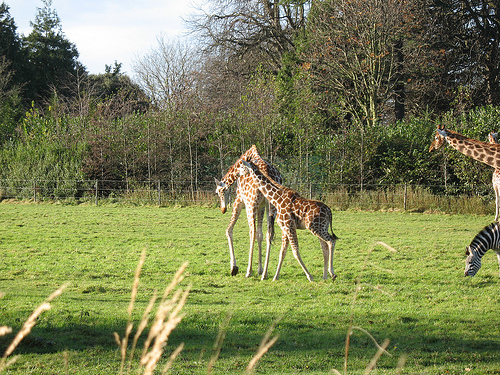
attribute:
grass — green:
[0, 189, 497, 372]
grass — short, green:
[5, 209, 221, 329]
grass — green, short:
[340, 214, 452, 366]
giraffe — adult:
[246, 192, 336, 275]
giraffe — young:
[195, 142, 263, 259]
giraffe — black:
[184, 142, 367, 289]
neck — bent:
[214, 140, 262, 210]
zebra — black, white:
[460, 224, 499, 280]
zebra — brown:
[435, 220, 498, 292]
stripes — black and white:
[469, 230, 499, 254]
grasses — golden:
[0, 234, 475, 371]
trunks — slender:
[142, 120, 201, 197]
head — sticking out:
[464, 252, 484, 280]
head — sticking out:
[423, 124, 452, 155]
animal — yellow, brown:
[241, 160, 341, 283]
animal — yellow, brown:
[209, 135, 280, 279]